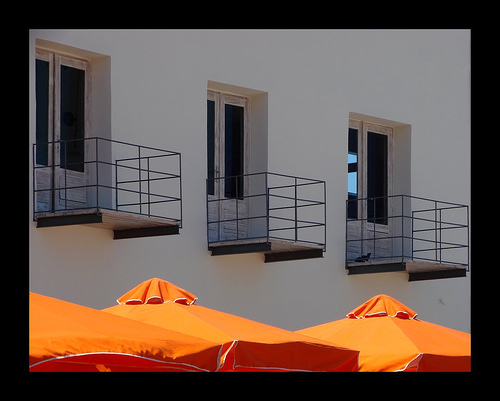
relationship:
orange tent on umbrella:
[100, 276, 356, 370] [100, 280, 388, 398]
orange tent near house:
[289, 290, 468, 373] [31, 33, 445, 321]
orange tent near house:
[100, 276, 356, 370] [31, 33, 445, 321]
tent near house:
[30, 290, 219, 372] [31, 33, 445, 321]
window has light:
[349, 129, 357, 219] [348, 154, 355, 192]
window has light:
[349, 129, 356, 219] [347, 150, 357, 192]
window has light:
[349, 129, 357, 219] [348, 152, 356, 193]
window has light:
[225, 102, 243, 197] [348, 152, 356, 193]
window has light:
[207, 100, 214, 194] [348, 152, 356, 193]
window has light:
[366, 130, 387, 224] [348, 152, 356, 193]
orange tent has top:
[100, 276, 356, 370] [113, 270, 198, 309]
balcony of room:
[203, 172, 325, 262] [207, 81, 248, 204]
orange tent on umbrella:
[289, 290, 468, 373] [314, 295, 462, 385]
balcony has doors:
[343, 192, 468, 265] [347, 122, 395, 256]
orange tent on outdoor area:
[289, 290, 468, 373] [31, 35, 468, 367]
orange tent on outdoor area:
[100, 276, 356, 370] [31, 35, 468, 367]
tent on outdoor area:
[30, 290, 219, 372] [31, 35, 468, 367]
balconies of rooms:
[32, 137, 183, 236] [32, 39, 115, 204]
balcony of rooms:
[210, 168, 325, 240] [203, 82, 274, 237]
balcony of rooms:
[343, 192, 468, 260] [349, 115, 410, 249]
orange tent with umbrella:
[112, 274, 201, 315] [64, 217, 333, 399]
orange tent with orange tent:
[100, 276, 356, 370] [340, 290, 415, 320]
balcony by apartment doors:
[343, 192, 468, 265] [201, 72, 279, 236]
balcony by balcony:
[343, 192, 468, 265] [203, 172, 325, 262]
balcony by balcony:
[343, 192, 468, 265] [34, 134, 183, 239]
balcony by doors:
[343, 192, 468, 265] [36, 40, 96, 206]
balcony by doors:
[343, 192, 468, 265] [205, 89, 252, 239]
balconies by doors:
[32, 137, 183, 236] [28, 45, 93, 213]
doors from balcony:
[336, 110, 404, 267] [344, 192, 478, 291]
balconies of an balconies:
[32, 137, 190, 237] [201, 160, 343, 271]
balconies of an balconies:
[32, 137, 190, 237] [336, 186, 473, 286]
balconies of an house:
[32, 137, 190, 237] [32, 27, 457, 339]